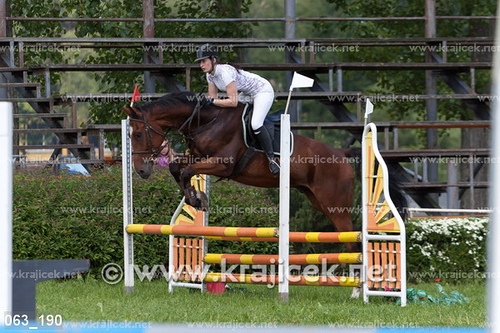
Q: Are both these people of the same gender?
A: Yes, all the people are female.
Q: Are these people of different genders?
A: No, all the people are female.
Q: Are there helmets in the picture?
A: Yes, there is a helmet.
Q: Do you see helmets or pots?
A: Yes, there is a helmet.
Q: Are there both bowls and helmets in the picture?
A: No, there is a helmet but no bowls.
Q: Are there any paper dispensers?
A: No, there are no paper dispensers.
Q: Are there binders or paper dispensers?
A: No, there are no paper dispensers or binders.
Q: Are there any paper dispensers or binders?
A: No, there are no paper dispensers or binders.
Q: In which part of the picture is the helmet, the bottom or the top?
A: The helmet is in the top of the image.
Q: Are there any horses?
A: Yes, there is a horse.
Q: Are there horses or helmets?
A: Yes, there is a horse.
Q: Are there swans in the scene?
A: No, there are no swans.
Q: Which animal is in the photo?
A: The animal is a horse.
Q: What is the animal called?
A: The animal is a horse.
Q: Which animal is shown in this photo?
A: The animal is a horse.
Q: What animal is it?
A: The animal is a horse.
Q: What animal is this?
A: This is a horse.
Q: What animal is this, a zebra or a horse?
A: This is a horse.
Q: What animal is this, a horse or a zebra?
A: This is a horse.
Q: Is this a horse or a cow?
A: This is a horse.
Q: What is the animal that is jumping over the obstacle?
A: The animal is a horse.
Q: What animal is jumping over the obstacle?
A: The animal is a horse.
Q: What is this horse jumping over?
A: The horse is jumping over the obstacle.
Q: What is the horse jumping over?
A: The horse is jumping over the obstacle.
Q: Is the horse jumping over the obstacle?
A: Yes, the horse is jumping over the obstacle.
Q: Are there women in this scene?
A: Yes, there is a woman.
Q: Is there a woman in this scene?
A: Yes, there is a woman.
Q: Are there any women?
A: Yes, there is a woman.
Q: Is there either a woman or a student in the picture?
A: Yes, there is a woman.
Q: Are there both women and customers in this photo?
A: No, there is a woman but no customers.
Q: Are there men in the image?
A: No, there are no men.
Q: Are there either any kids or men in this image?
A: No, there are no men or kids.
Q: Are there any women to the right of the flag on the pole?
A: Yes, there is a woman to the right of the flag.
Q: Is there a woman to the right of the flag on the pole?
A: Yes, there is a woman to the right of the flag.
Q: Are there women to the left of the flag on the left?
A: No, the woman is to the right of the flag.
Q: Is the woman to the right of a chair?
A: No, the woman is to the right of the flag.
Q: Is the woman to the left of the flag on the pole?
A: No, the woman is to the right of the flag.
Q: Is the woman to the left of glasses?
A: No, the woman is to the left of the flags.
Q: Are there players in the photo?
A: No, there are no players.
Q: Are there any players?
A: No, there are no players.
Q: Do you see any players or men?
A: No, there are no players or men.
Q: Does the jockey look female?
A: Yes, the jockey is female.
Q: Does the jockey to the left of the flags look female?
A: Yes, the jockey is female.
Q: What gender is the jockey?
A: The jockey is female.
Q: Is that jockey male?
A: No, the jockey is female.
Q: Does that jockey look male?
A: No, the jockey is female.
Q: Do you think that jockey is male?
A: No, the jockey is female.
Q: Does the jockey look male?
A: No, the jockey is female.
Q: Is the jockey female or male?
A: The jockey is female.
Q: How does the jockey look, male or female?
A: The jockey is female.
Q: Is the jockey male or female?
A: The jockey is female.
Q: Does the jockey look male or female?
A: The jockey is female.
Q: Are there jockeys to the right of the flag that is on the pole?
A: Yes, there is a jockey to the right of the flag.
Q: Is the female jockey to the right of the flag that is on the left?
A: Yes, the jockey is to the right of the flag.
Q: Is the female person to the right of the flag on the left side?
A: Yes, the jockey is to the right of the flag.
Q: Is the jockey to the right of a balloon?
A: No, the jockey is to the right of the flag.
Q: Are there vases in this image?
A: No, there are no vases.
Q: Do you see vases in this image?
A: No, there are no vases.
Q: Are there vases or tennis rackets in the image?
A: No, there are no vases or tennis rackets.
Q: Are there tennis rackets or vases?
A: No, there are no vases or tennis rackets.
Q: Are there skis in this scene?
A: No, there are no skis.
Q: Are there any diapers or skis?
A: No, there are no skis or diapers.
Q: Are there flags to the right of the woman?
A: Yes, there are flags to the right of the woman.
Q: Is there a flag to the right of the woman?
A: Yes, there are flags to the right of the woman.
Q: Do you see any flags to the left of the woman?
A: No, the flags are to the right of the woman.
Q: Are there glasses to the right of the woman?
A: No, there are flags to the right of the woman.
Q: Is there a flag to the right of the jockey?
A: Yes, there are flags to the right of the jockey.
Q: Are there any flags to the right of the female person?
A: Yes, there are flags to the right of the jockey.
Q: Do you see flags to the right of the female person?
A: Yes, there are flags to the right of the jockey.